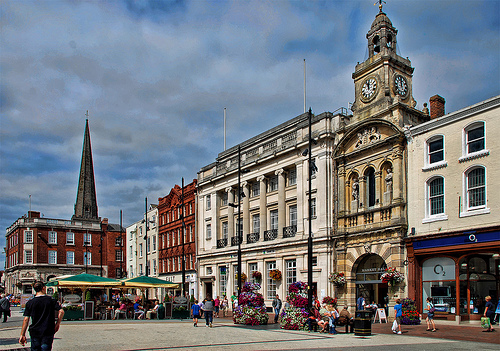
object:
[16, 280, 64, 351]
man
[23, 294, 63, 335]
shirt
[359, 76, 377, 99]
clock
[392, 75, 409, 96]
clock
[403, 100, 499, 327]
building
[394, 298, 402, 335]
person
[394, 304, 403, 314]
shirt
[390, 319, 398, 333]
bag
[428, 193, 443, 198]
window bars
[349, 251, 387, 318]
door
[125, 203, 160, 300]
building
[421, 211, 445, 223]
window pane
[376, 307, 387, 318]
sign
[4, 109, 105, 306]
building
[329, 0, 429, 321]
building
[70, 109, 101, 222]
gray spire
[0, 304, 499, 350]
walkway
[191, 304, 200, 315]
blue shirt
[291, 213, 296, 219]
windows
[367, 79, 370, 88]
hands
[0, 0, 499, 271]
blue sky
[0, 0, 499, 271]
clouds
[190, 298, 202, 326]
people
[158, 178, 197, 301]
building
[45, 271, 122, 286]
tent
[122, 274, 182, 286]
tent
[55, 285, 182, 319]
seating area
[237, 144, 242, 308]
pole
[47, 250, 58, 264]
windows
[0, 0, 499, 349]
district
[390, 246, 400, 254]
brick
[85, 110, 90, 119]
crucifix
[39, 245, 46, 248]
brick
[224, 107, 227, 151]
mast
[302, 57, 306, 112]
mast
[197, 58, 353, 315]
building